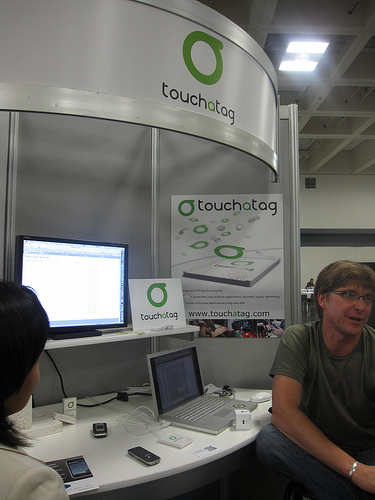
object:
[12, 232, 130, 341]
computer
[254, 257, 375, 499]
man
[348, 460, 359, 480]
bracelet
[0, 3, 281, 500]
display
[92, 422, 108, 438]
cellphone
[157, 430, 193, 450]
touch pad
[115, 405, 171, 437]
cord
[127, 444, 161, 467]
cellphone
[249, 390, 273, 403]
mouse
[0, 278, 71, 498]
woman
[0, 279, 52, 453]
hair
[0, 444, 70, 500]
jacket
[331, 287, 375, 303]
eyeglasses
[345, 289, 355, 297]
eyes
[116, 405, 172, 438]
cable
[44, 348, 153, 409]
long cord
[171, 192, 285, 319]
advertising sign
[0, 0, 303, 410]
wall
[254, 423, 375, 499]
leg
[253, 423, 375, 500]
jeans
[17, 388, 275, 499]
deks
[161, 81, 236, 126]
touchatag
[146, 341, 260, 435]
laptop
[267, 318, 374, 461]
shirt